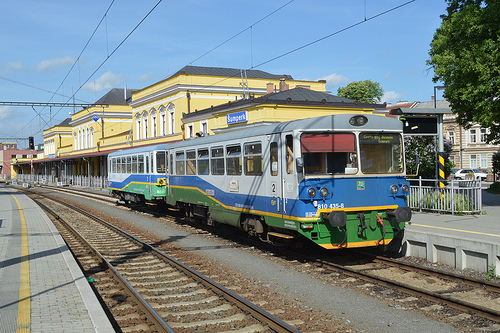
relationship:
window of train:
[222, 139, 241, 179] [102, 104, 420, 264]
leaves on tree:
[455, 70, 468, 80] [434, 12, 476, 93]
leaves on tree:
[441, 30, 470, 53] [435, 56, 474, 96]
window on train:
[244, 140, 265, 176] [107, 110, 409, 249]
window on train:
[360, 131, 404, 177] [102, 104, 420, 264]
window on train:
[196, 148, 208, 175] [107, 110, 409, 249]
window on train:
[174, 151, 188, 181] [108, 117, 417, 263]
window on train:
[266, 138, 279, 176] [102, 113, 419, 272]